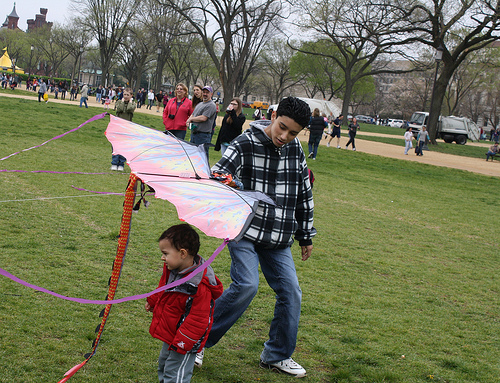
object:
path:
[0, 81, 499, 179]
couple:
[400, 125, 431, 157]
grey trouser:
[155, 341, 197, 382]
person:
[162, 82, 191, 141]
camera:
[166, 114, 175, 122]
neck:
[173, 97, 186, 103]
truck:
[405, 109, 470, 146]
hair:
[273, 94, 311, 130]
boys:
[190, 95, 316, 378]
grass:
[0, 95, 498, 382]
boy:
[144, 223, 226, 383]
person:
[413, 125, 431, 156]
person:
[400, 127, 415, 157]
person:
[343, 115, 359, 151]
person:
[323, 114, 342, 152]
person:
[302, 107, 327, 162]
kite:
[0, 111, 277, 383]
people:
[75, 80, 89, 109]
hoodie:
[208, 118, 318, 251]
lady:
[213, 97, 246, 155]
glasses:
[228, 102, 238, 107]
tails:
[0, 238, 231, 308]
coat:
[145, 256, 224, 356]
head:
[154, 221, 200, 272]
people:
[183, 86, 217, 163]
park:
[0, 0, 498, 382]